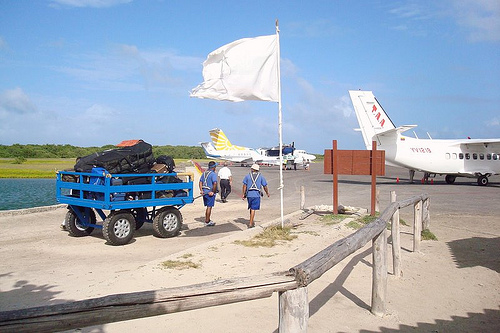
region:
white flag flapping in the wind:
[187, 33, 280, 105]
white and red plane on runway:
[347, 87, 498, 185]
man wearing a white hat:
[250, 163, 258, 170]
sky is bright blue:
[0, 0, 499, 152]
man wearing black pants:
[220, 177, 230, 197]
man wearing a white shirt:
[216, 168, 232, 178]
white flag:
[198, 38, 289, 106]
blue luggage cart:
[57, 149, 182, 231]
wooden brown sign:
[321, 142, 385, 207]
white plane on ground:
[355, 93, 497, 177]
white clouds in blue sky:
[350, 18, 398, 39]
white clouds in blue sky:
[414, 22, 491, 67]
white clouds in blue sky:
[292, 55, 334, 100]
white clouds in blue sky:
[31, 23, 89, 60]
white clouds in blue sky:
[24, 79, 92, 119]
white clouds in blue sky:
[118, 48, 168, 85]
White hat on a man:
[247, 160, 258, 170]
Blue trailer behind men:
[51, 165, 192, 201]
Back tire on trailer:
[100, 210, 130, 240]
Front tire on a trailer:
[150, 201, 180, 228]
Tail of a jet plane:
[347, 85, 387, 145]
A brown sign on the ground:
[325, 136, 382, 211]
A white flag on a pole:
[198, 38, 281, 105]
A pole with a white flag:
[196, 13, 288, 219]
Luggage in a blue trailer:
[82, 140, 172, 183]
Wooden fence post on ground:
[276, 288, 311, 332]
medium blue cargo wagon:
[53, 164, 205, 244]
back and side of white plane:
[343, 75, 498, 192]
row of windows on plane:
[443, 150, 498, 162]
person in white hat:
[236, 162, 271, 229]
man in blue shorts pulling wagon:
[195, 158, 221, 225]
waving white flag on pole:
[187, 18, 293, 235]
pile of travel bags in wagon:
[65, 134, 187, 207]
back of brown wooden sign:
[317, 134, 393, 223]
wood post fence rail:
[2, 192, 437, 332]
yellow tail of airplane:
[205, 121, 252, 156]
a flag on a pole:
[224, 20, 324, 186]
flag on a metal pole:
[212, 18, 308, 140]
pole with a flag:
[233, 15, 308, 130]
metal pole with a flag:
[227, 25, 302, 161]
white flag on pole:
[210, 23, 317, 143]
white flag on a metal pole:
[211, 20, 326, 168]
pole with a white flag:
[201, 25, 351, 148]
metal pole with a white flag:
[199, 20, 322, 143]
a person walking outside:
[247, 158, 266, 239]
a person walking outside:
[194, 160, 216, 227]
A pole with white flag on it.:
[187, 18, 284, 229]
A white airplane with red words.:
[347, 89, 499, 187]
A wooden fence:
[0, 192, 430, 332]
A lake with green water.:
[0, 176, 70, 209]